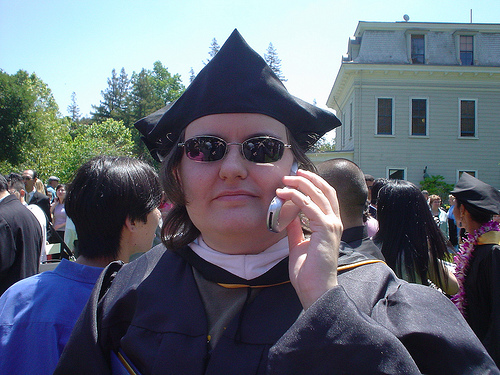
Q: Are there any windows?
A: Yes, there is a window.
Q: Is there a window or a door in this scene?
A: Yes, there is a window.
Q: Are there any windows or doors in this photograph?
A: Yes, there is a window.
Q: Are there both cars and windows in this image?
A: No, there is a window but no cars.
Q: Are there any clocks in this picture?
A: No, there are no clocks.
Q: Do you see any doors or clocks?
A: No, there are no clocks or doors.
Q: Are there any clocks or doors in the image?
A: No, there are no clocks or doors.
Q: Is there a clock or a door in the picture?
A: No, there are no clocks or doors.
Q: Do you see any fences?
A: No, there are no fences.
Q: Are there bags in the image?
A: No, there are no bags.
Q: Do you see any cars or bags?
A: No, there are no bags or cars.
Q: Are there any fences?
A: No, there are no fences.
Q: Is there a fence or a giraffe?
A: No, there are no fences or giraffes.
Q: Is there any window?
A: Yes, there is a window.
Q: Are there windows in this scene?
A: Yes, there is a window.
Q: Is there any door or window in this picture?
A: Yes, there is a window.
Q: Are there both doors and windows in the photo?
A: No, there is a window but no doors.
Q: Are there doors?
A: No, there are no doors.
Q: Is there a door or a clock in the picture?
A: No, there are no doors or clocks.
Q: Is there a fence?
A: No, there are no fences.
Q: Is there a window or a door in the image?
A: Yes, there is a window.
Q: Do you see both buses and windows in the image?
A: No, there is a window but no buses.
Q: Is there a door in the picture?
A: No, there are no doors.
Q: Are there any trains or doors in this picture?
A: No, there are no doors or trains.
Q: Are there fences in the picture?
A: No, there are no fences.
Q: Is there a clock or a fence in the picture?
A: No, there are no fences or clocks.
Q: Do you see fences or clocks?
A: No, there are no fences or clocks.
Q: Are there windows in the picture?
A: Yes, there is a window.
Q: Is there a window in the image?
A: Yes, there is a window.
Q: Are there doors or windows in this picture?
A: Yes, there is a window.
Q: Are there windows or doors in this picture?
A: Yes, there is a window.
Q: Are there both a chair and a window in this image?
A: No, there is a window but no chairs.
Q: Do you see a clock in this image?
A: No, there are no clocks.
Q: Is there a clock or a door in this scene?
A: No, there are no clocks or doors.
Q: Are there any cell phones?
A: Yes, there is a cell phone.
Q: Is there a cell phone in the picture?
A: Yes, there is a cell phone.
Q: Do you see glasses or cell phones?
A: Yes, there is a cell phone.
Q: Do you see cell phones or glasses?
A: Yes, there is a cell phone.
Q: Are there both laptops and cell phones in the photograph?
A: No, there is a cell phone but no laptops.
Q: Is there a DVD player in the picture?
A: No, there are no DVD players.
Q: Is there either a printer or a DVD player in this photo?
A: No, there are no DVD players or printers.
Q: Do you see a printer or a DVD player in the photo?
A: No, there are no DVD players or printers.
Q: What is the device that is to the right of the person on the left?
A: The device is a cell phone.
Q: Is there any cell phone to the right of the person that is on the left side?
A: Yes, there is a cell phone to the right of the person.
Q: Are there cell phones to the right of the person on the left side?
A: Yes, there is a cell phone to the right of the person.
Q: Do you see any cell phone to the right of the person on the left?
A: Yes, there is a cell phone to the right of the person.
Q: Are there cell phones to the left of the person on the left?
A: No, the cell phone is to the right of the person.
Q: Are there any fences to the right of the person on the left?
A: No, there is a cell phone to the right of the person.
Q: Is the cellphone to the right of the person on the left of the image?
A: Yes, the cellphone is to the right of the person.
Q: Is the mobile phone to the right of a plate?
A: No, the mobile phone is to the right of the person.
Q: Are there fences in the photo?
A: No, there are no fences.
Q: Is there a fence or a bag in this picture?
A: No, there are no fences or bags.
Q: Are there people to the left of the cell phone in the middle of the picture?
A: Yes, there is a person to the left of the cellphone.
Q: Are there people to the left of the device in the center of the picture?
A: Yes, there is a person to the left of the cellphone.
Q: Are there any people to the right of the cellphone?
A: No, the person is to the left of the cellphone.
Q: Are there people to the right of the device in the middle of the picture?
A: No, the person is to the left of the cellphone.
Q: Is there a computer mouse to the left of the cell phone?
A: No, there is a person to the left of the cell phone.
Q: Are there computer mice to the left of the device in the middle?
A: No, there is a person to the left of the cell phone.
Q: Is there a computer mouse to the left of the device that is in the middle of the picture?
A: No, there is a person to the left of the cell phone.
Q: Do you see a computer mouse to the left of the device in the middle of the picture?
A: No, there is a person to the left of the cell phone.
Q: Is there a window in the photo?
A: Yes, there is a window.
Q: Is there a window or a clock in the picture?
A: Yes, there is a window.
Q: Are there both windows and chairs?
A: No, there is a window but no chairs.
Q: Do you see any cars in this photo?
A: No, there are no cars.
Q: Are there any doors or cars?
A: No, there are no cars or doors.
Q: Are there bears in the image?
A: No, there are no bears.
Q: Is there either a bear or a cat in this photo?
A: No, there are no bears or cats.